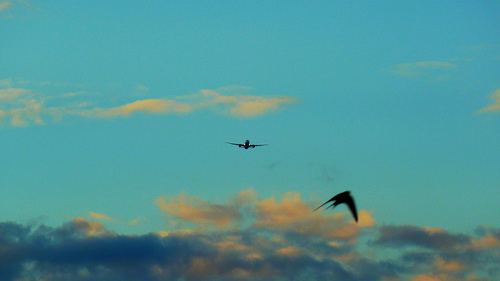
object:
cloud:
[2, 186, 497, 278]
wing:
[308, 196, 336, 213]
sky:
[2, 1, 499, 279]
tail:
[324, 204, 338, 210]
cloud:
[5, 80, 298, 123]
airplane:
[222, 138, 268, 150]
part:
[236, 142, 242, 146]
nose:
[246, 139, 250, 141]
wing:
[340, 195, 365, 224]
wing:
[253, 143, 269, 148]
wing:
[223, 141, 242, 148]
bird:
[310, 189, 357, 223]